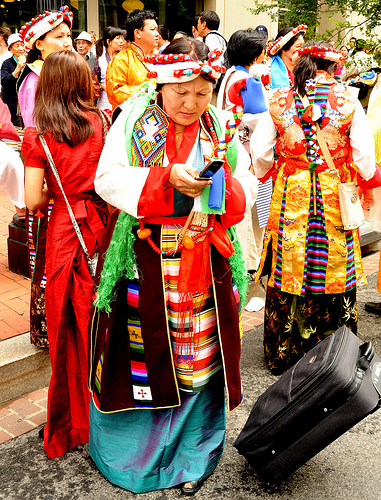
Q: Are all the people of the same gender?
A: Yes, all the people are female.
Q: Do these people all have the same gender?
A: Yes, all the people are female.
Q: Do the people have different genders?
A: No, all the people are female.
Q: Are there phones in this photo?
A: Yes, there is a phone.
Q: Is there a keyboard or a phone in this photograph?
A: Yes, there is a phone.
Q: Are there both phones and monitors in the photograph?
A: No, there is a phone but no monitors.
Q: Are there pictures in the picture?
A: No, there are no pictures.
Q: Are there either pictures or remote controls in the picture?
A: No, there are no pictures or remote controls.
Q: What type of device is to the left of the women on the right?
A: The device is a phone.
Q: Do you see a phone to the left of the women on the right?
A: Yes, there is a phone to the left of the women.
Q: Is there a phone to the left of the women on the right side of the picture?
A: Yes, there is a phone to the left of the women.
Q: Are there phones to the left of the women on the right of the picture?
A: Yes, there is a phone to the left of the women.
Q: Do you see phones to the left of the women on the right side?
A: Yes, there is a phone to the left of the women.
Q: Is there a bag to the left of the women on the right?
A: No, there is a phone to the left of the women.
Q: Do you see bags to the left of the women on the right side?
A: No, there is a phone to the left of the women.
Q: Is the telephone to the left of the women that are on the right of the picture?
A: Yes, the telephone is to the left of the women.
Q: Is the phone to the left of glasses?
A: No, the phone is to the left of the women.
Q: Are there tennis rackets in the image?
A: No, there are no tennis rackets.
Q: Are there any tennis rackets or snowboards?
A: No, there are no tennis rackets or snowboards.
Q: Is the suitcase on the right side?
A: Yes, the suitcase is on the right of the image.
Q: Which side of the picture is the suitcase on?
A: The suitcase is on the right of the image.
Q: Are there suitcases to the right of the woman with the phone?
A: Yes, there is a suitcase to the right of the woman.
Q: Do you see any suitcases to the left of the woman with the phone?
A: No, the suitcase is to the right of the woman.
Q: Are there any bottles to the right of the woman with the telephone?
A: No, there is a suitcase to the right of the woman.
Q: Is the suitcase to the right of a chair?
A: No, the suitcase is to the right of the woman.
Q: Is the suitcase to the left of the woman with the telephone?
A: No, the suitcase is to the right of the woman.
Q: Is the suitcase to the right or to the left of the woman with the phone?
A: The suitcase is to the right of the woman.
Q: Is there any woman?
A: Yes, there is a woman.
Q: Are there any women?
A: Yes, there is a woman.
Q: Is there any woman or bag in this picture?
A: Yes, there is a woman.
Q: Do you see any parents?
A: No, there are no parents.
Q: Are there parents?
A: No, there are no parents.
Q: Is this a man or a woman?
A: This is a woman.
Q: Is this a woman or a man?
A: This is a woman.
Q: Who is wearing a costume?
A: The woman is wearing a costume.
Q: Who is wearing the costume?
A: The woman is wearing a costume.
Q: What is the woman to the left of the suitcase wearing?
A: The woman is wearing a costume.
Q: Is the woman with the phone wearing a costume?
A: Yes, the woman is wearing a costume.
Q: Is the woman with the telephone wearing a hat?
A: No, the woman is wearing a costume.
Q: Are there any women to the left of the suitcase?
A: Yes, there is a woman to the left of the suitcase.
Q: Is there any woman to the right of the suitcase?
A: No, the woman is to the left of the suitcase.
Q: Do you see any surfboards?
A: No, there are no surfboards.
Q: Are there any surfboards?
A: No, there are no surfboards.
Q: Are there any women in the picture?
A: Yes, there are women.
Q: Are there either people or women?
A: Yes, there are women.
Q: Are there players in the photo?
A: No, there are no players.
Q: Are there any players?
A: No, there are no players.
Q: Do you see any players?
A: No, there are no players.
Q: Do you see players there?
A: No, there are no players.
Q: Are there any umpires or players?
A: No, there are no players or umpires.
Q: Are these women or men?
A: These are women.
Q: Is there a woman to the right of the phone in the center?
A: Yes, there are women to the right of the phone.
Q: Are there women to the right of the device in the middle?
A: Yes, there are women to the right of the phone.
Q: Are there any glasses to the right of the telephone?
A: No, there are women to the right of the telephone.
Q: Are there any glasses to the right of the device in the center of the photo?
A: No, there are women to the right of the telephone.